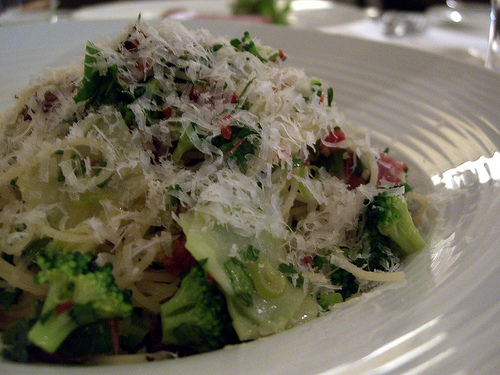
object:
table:
[0, 0, 500, 71]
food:
[1, 14, 429, 368]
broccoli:
[24, 251, 133, 355]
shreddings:
[7, 12, 343, 266]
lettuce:
[178, 217, 323, 339]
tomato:
[370, 153, 409, 185]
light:
[429, 151, 500, 191]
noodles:
[118, 274, 181, 313]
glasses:
[360, 0, 499, 72]